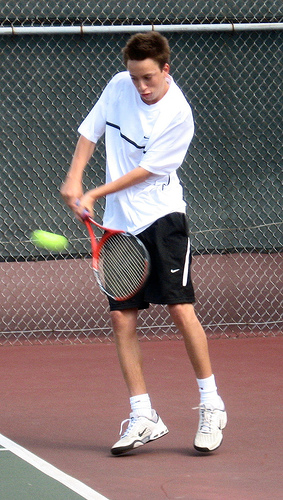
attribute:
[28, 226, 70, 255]
tennis ball — green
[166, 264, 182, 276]
check — white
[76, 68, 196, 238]
shirt — white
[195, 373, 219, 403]
sock — white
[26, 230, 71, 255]
tennis ball — yellow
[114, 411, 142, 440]
laces — white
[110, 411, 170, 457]
sneakers — white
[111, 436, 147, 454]
edge — black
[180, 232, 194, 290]
line — white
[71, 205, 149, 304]
tennis racket — red, blue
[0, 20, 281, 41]
pole — silver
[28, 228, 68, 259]
tennis ball — yellow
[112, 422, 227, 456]
trim — black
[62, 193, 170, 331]
tennis racket — red, black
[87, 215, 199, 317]
shorts — black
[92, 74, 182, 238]
shirt — white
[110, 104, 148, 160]
stripe — black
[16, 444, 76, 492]
line — white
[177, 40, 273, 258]
fence — tall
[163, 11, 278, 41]
pipe — horizontal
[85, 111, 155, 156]
stripe — horizontal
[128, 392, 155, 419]
sock — white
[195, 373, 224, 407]
sock — white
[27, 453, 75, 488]
line — white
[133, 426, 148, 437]
mark — black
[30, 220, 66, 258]
tennis ball — yellow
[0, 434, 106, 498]
line — bold, white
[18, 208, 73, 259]
ball — yellow, tennis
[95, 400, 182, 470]
sneaker — white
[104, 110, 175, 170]
stripe — black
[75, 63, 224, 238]
shirt — white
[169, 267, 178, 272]
check mark — white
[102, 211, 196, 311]
shorts — black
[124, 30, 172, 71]
hair — man's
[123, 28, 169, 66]
spikey hair — brown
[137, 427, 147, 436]
swoosh symbol — black, Nike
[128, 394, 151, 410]
sock — white, scrunched up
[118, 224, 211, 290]
shorts — black, white, striped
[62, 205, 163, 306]
racket — red